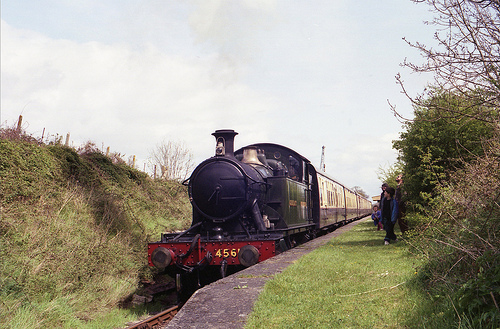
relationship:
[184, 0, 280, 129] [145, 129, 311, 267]
smoke from engine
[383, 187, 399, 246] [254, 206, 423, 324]
person are in field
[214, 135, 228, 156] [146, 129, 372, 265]
bell on train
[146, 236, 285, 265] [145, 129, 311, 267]
cow catcher on engine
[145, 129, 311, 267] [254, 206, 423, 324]
engine in field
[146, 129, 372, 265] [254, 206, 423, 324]
train traveling through field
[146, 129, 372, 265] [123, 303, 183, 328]
train on train track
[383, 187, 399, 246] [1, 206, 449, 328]
person are on grass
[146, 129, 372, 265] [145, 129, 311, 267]
train has engine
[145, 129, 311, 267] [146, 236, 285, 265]
engine has trim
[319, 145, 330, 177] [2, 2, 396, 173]
crane in background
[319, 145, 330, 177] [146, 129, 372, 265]
crane behind train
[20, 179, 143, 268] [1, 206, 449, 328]
weeds in grass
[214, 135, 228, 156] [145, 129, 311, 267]
bell on engine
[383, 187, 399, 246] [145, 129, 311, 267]
person are beside engine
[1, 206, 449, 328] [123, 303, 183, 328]
grass beside train track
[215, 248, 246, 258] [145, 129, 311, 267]
numbers on front of engine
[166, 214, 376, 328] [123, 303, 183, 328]
path beside train track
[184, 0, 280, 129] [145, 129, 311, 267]
smoke coming from engine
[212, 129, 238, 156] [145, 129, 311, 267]
smoke stack on engine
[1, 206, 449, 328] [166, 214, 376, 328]
grass growin on path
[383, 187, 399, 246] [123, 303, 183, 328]
person beside train track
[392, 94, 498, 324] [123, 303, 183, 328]
bushes beside train track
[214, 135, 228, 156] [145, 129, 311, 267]
bell on top of engine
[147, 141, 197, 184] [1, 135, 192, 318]
tree branches behind hillside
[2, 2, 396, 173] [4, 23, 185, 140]
background has clouds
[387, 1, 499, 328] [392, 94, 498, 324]
sideview of bushes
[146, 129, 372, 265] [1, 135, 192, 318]
train near hillside